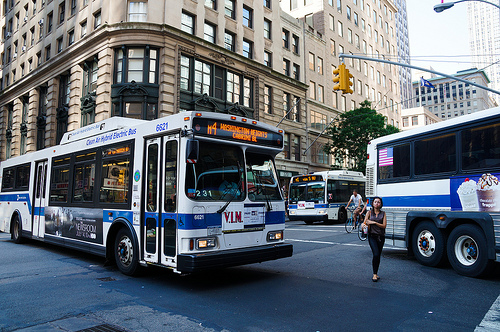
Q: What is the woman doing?
A: Crossing the street.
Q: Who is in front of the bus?
A: A woman.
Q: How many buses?
A: 3.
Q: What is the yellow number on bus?
A: 4.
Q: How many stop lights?
A: 1.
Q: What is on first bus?
A: Ice cream.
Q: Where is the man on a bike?
A: Behind bus.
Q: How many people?
A: 2.